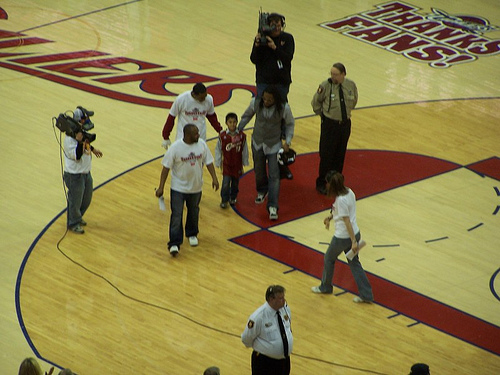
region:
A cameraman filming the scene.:
[48, 97, 104, 239]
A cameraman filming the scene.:
[255, 6, 300, 183]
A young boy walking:
[219, 110, 250, 218]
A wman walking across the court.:
[303, 167, 373, 315]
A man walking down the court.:
[161, 116, 212, 263]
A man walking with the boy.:
[245, 88, 296, 232]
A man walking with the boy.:
[167, 81, 223, 149]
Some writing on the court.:
[317, 2, 498, 74]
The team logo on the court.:
[1, 25, 257, 128]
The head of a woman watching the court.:
[13, 356, 52, 374]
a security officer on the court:
[263, 294, 283, 355]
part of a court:
[130, 297, 169, 327]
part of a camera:
[78, 127, 88, 129]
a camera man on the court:
[43, 110, 94, 252]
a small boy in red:
[221, 120, 244, 177]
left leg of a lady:
[321, 261, 330, 306]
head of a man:
[318, 69, 344, 86]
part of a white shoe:
[271, 206, 273, 220]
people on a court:
[78, 6, 413, 273]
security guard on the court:
[238, 261, 309, 358]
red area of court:
[285, 141, 426, 210]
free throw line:
[383, 171, 434, 207]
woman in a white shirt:
[301, 172, 371, 271]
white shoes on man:
[150, 228, 210, 286]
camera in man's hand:
[39, 93, 116, 172]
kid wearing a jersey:
[212, 109, 259, 161]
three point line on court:
[8, 240, 48, 302]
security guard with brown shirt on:
[304, 43, 404, 137]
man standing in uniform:
[302, 61, 384, 190]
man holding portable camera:
[34, 85, 127, 252]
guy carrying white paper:
[133, 112, 223, 279]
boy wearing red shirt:
[210, 110, 247, 235]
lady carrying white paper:
[298, 156, 381, 292]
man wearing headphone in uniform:
[234, 285, 327, 374]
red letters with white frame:
[314, 4, 498, 81]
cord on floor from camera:
[42, 110, 111, 298]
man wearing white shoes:
[153, 121, 235, 258]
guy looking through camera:
[240, 2, 315, 102]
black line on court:
[96, 267, 179, 319]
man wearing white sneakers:
[153, 223, 213, 278]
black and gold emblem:
[241, 318, 276, 344]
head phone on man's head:
[243, 275, 307, 322]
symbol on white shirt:
[171, 141, 223, 187]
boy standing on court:
[209, 106, 251, 188]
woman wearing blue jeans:
[313, 228, 374, 304]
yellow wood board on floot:
[383, 113, 467, 141]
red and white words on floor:
[318, 11, 458, 85]